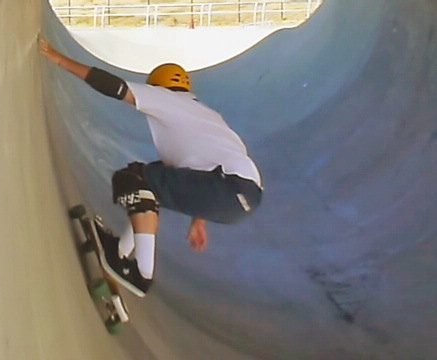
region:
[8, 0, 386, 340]
a boy skateboarding in a park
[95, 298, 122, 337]
a rubber wheel on a skateboard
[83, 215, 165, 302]
skateboarding tennis shoes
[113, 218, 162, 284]
a pair of white socks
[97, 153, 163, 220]
skateboarding knee protectors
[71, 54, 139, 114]
skateboarding elbow protectors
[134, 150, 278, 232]
men's shorts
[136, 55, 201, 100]
a man's yellow helmet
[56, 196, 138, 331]
a wooden skateboard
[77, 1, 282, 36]
rails at a skateboard park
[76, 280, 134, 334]
Green rear wheels of a skateboard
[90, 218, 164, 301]
A pair of black sneakers with white soles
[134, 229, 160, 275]
A white sock on a foot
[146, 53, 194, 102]
A person wearing an orange helmet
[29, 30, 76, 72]
A hand holding onto the wall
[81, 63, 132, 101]
A black ace bandon the elbow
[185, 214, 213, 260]
a right hand hanging down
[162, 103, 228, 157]
A white tee shirt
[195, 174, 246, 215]
a pair of blue pants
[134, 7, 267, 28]
A white metal fence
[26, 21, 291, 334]
The person is on a skateboard.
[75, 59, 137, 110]
The person is wearing elbows pads.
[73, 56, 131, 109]
The elbow pads are black.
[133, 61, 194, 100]
The person is wearing a helmet.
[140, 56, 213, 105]
The helmet is yellow.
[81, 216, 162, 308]
The person is wearing black shoes.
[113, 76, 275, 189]
The person is wearing a white top.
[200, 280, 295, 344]
The ground is gray.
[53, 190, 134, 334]
The skateboard has green wheels.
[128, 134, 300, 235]
The person is wearing shorts.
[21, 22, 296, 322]
One boy is skating.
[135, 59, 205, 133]
Boy is wearing helmet.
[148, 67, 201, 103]
helmet is yellow color.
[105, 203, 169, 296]
Boy is white socks.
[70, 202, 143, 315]
Skateboard is black color.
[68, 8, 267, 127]
Day time picture.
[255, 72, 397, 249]
Half pipe is grey color.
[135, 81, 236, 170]
Boy is wearing white shirt.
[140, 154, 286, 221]
Boy is wearing blue shorts.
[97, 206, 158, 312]
Boy is wearing black shoes.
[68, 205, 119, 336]
skateboard has four wheels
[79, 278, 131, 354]
wheels are green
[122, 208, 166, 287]
skater is wearing white socks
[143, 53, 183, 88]
skater is wearing a yellow helmet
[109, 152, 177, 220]
skater has on knee pads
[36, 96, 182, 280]
skater is on side of ramp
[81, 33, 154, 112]
skater is wearing a elbow pad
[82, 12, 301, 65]
light at the end fo ramp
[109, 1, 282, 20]
fence is white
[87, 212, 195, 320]
skater's tennis shoes are black